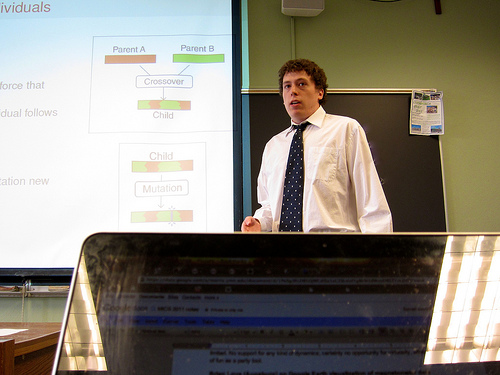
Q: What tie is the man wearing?
A: Long tie.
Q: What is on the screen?
A: Presentation.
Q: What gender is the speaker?
A: Male.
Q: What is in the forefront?
A: Laptop screen.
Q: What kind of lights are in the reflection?
A: Fluorescent.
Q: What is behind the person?
A: Blackboard.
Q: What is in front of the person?
A: Computer screen.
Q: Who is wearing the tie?
A: Man in white shirt.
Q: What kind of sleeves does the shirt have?
A: Long.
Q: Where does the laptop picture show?
A: On screen.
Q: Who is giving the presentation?
A: The man standing by the screen.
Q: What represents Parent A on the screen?
A: A long, red box.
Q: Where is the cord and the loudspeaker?
A: Above the man's head.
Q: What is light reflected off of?
A: Laptop.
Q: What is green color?
A: Wall.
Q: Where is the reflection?
A: In screen.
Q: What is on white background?
A: Presentation.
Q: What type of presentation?
A: Flow chart.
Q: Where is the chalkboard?
A: Behind kid.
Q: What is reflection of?
A: Lights.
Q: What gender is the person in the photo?
A: Male.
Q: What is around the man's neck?
A: A tie.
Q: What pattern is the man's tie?
A: Polka dot.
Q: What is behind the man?
A: A chalkboard.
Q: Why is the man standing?
A: He is giving a presentation.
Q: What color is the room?
A: Green.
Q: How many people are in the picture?
A: One.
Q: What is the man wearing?
A: A dress shirt and tie.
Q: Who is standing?
A: A man.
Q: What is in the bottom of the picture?
A: A laptop.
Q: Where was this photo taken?
A: A class.